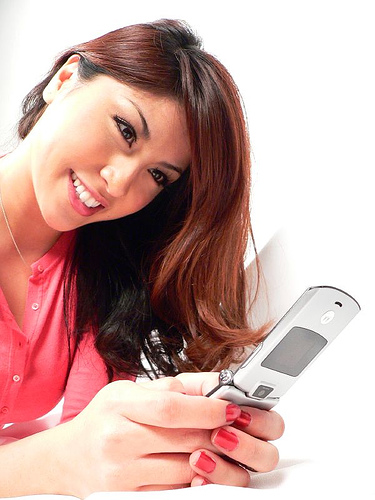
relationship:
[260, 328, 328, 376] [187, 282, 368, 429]
window on phone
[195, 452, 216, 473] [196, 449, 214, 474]
polish on nail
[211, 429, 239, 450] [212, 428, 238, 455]
polish on fingernail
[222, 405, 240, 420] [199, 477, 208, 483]
polish on nail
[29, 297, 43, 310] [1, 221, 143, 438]
button on blouse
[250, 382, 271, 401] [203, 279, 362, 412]
camera on phone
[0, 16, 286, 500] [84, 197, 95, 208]
girl has teeth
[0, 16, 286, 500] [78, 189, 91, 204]
girl has teeth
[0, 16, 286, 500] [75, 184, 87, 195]
girl has teeth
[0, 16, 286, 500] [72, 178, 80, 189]
girl has teeth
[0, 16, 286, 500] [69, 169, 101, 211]
girl has human tooth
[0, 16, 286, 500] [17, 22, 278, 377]
girl has hair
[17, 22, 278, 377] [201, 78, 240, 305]
hair has highlights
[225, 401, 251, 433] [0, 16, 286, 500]
fingernail on girl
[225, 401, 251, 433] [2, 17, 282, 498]
fingernail on person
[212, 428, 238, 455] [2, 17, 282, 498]
fingernail on person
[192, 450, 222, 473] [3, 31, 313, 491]
red fingernail on person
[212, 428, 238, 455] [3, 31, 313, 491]
fingernail on person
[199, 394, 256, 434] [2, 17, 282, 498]
fingernail on person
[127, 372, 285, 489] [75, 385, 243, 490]
finger on hand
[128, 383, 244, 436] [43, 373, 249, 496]
finger on hand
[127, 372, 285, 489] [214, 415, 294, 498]
finger on hand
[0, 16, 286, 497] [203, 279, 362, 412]
girl holding phone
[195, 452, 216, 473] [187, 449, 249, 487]
polish on finger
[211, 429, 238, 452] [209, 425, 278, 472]
polish on finger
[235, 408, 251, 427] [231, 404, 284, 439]
nailpolish on finger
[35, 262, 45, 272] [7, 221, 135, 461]
button unbuttoned on top of shirt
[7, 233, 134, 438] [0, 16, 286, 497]
shirt worn by girl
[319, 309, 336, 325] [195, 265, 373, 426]
motorola symbol on phone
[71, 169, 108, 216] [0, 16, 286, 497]
smile on girl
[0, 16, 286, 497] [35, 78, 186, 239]
girl has face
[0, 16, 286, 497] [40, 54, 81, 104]
girl has ear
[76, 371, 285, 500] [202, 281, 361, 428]
hand holding onto phone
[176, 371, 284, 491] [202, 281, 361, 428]
hand holding onto phone